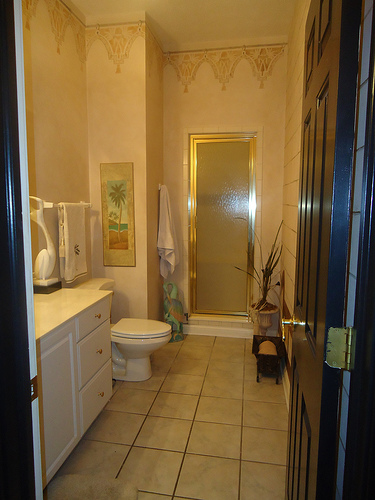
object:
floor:
[169, 393, 252, 450]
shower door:
[196, 138, 249, 310]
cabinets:
[74, 300, 114, 439]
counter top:
[52, 294, 86, 312]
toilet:
[112, 312, 169, 380]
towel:
[61, 201, 91, 283]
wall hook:
[84, 201, 93, 215]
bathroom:
[17, 0, 375, 499]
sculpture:
[157, 277, 190, 342]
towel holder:
[48, 198, 94, 210]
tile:
[128, 410, 176, 459]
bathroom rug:
[50, 475, 140, 500]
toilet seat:
[111, 317, 169, 334]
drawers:
[73, 318, 113, 438]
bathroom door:
[283, 0, 344, 500]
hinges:
[326, 324, 358, 372]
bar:
[45, 200, 61, 209]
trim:
[187, 132, 259, 144]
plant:
[232, 213, 282, 309]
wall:
[168, 66, 266, 98]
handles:
[95, 310, 104, 324]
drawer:
[77, 300, 111, 342]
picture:
[100, 160, 138, 271]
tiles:
[173, 357, 239, 398]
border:
[162, 43, 284, 61]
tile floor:
[122, 445, 156, 477]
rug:
[59, 479, 97, 500]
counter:
[37, 303, 68, 328]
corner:
[273, 204, 287, 226]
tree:
[104, 180, 129, 211]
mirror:
[194, 139, 250, 313]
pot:
[248, 304, 279, 332]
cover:
[109, 315, 170, 336]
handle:
[278, 316, 300, 345]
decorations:
[24, 0, 146, 78]